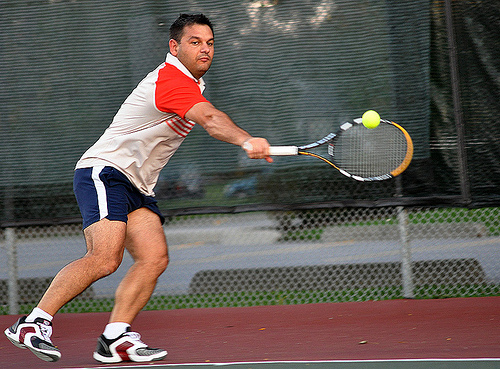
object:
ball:
[361, 110, 381, 130]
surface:
[0, 293, 498, 367]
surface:
[96, 360, 497, 366]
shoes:
[90, 324, 169, 363]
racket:
[268, 117, 413, 184]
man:
[2, 10, 274, 363]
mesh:
[6, 1, 430, 187]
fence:
[3, 0, 499, 293]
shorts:
[72, 165, 166, 231]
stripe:
[90, 165, 109, 219]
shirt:
[73, 52, 207, 197]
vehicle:
[218, 179, 258, 203]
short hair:
[170, 13, 214, 23]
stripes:
[161, 115, 194, 138]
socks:
[24, 306, 52, 322]